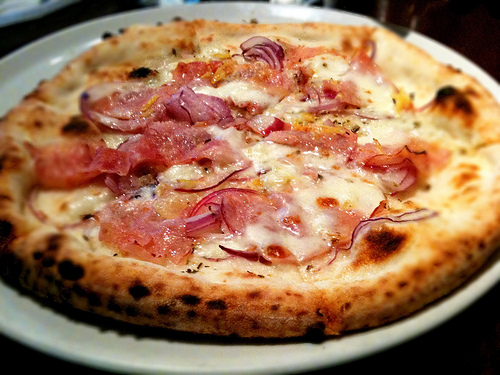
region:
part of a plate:
[333, 323, 359, 352]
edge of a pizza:
[224, 280, 238, 292]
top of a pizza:
[216, 254, 250, 289]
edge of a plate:
[52, 312, 108, 342]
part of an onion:
[156, 185, 162, 222]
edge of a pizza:
[82, 263, 87, 288]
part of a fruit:
[58, 163, 73, 173]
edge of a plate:
[93, 328, 130, 349]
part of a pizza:
[351, 173, 386, 205]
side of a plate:
[85, 333, 112, 345]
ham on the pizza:
[163, 86, 210, 118]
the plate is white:
[118, 335, 181, 373]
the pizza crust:
[265, 292, 355, 337]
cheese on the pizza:
[221, 81, 263, 101]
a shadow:
[85, 313, 135, 341]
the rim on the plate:
[36, 344, 87, 366]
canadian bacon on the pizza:
[110, 210, 187, 261]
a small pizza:
[40, 15, 455, 306]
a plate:
[20, 48, 52, 83]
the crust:
[164, 281, 289, 336]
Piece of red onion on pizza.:
[250, 35, 272, 70]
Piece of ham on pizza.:
[182, 90, 206, 114]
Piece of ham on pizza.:
[117, 87, 149, 126]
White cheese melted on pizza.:
[196, 63, 347, 268]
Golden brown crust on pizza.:
[107, 250, 239, 327]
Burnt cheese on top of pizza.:
[366, 223, 390, 250]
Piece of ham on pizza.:
[359, 135, 416, 197]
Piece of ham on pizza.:
[47, 128, 109, 188]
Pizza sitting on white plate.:
[18, 61, 395, 326]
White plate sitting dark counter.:
[227, 227, 452, 352]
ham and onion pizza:
[7, 25, 499, 320]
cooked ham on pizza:
[87, 91, 234, 127]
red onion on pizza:
[156, 205, 226, 229]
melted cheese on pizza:
[255, 145, 376, 230]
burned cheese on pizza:
[433, 87, 476, 129]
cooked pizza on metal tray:
[13, 20, 499, 332]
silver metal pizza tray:
[1, 4, 497, 369]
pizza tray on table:
[2, 7, 499, 374]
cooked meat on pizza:
[75, 131, 245, 180]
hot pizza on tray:
[2, 20, 499, 338]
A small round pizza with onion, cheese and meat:
[0, 17, 499, 342]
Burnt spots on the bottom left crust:
[1, 221, 154, 331]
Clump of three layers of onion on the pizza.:
[239, 35, 283, 69]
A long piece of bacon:
[38, 120, 233, 188]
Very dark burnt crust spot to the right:
[436, 85, 476, 122]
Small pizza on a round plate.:
[0, 20, 499, 336]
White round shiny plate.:
[0, 3, 497, 373]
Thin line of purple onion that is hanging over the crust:
[329, 203, 438, 263]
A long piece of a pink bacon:
[39, 119, 236, 187]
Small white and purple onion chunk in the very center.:
[246, 110, 287, 140]